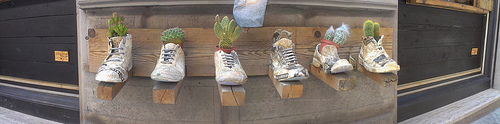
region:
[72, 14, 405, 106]
sneakers being used a pots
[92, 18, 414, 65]
the sneakers have cacti growing in them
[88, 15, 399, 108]
the shoes appear to be setting on wooden joists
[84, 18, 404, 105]
a unique display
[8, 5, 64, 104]
the background is black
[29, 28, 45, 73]
it appears to be boards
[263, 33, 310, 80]
this sneaker is black & white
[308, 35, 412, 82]
these two sneakers are black & white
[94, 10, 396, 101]
such an odd photo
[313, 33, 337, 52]
the cactus is in a clay pot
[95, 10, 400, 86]
Six tennis shoes with cactus growing inside.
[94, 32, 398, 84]
Six tennis shoes on display.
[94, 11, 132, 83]
A white shoe with black markings.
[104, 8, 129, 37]
A cactus growing in a tennis shoe.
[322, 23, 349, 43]
A blue cactus growing in a shoe.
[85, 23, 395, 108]
A wooden display with six shoes.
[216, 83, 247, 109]
A wooden beam holding up a shoe potted plant.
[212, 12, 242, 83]
A shoe potted plant.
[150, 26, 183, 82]
A white tennis shoe with a small cactus growing inside.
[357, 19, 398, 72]
An old shoe with a cactus growing inside.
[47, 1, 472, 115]
shoes on the wall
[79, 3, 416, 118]
shoes on a piece of wood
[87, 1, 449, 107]
shoes with plants in them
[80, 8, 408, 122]
shoes with cactuses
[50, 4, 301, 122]
plants in shoes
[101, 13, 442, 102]
shoes on a wall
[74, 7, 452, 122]
a wall with shoes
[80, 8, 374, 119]
wood with shoes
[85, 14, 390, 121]
six shoes in a row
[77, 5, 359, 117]
six shoes on a wall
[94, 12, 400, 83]
Six white shoes with plants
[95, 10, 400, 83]
Six shoes used as plant pots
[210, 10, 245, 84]
White tennis shoe with a cactus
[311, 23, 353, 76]
Casual shoe with a cactus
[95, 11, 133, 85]
High top sneaker plant pot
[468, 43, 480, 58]
Small rectangular gold plaque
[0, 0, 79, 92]
Black wood with gold trim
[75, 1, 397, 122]
Display of shoe shaped plant pots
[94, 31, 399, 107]
Six shoes resting on wood supports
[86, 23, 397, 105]
Light wood display shelf